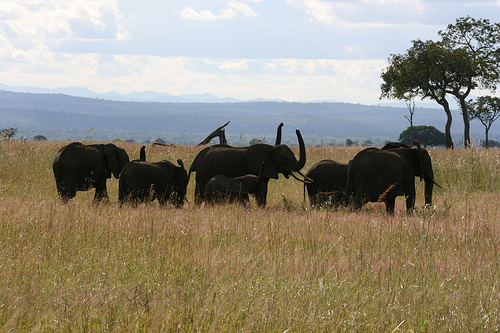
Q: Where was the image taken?
A: It was taken at the plain.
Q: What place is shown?
A: It is a plain.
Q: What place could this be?
A: It is a plain.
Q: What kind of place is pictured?
A: It is a plain.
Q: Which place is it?
A: It is a plain.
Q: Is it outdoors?
A: Yes, it is outdoors.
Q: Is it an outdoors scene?
A: Yes, it is outdoors.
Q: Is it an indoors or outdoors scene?
A: It is outdoors.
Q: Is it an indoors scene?
A: No, it is outdoors.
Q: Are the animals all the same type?
A: Yes, all the animals are elephants.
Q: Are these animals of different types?
A: No, all the animals are elephants.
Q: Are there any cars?
A: No, there are no cars.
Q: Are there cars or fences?
A: No, there are no cars or fences.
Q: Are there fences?
A: No, there are no fences.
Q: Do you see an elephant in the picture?
A: Yes, there is an elephant.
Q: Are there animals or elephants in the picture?
A: Yes, there is an elephant.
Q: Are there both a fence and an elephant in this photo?
A: No, there is an elephant but no fences.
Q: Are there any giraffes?
A: No, there are no giraffes.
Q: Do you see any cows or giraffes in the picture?
A: No, there are no giraffes or cows.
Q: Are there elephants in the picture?
A: Yes, there is an elephant.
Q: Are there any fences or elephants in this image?
A: Yes, there is an elephant.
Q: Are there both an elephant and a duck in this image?
A: No, there is an elephant but no ducks.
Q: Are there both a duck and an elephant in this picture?
A: No, there is an elephant but no ducks.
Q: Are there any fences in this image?
A: No, there are no fences.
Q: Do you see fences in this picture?
A: No, there are no fences.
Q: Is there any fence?
A: No, there are no fences.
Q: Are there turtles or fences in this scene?
A: No, there are no fences or turtles.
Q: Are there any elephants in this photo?
A: Yes, there is an elephant.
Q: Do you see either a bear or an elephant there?
A: Yes, there is an elephant.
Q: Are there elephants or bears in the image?
A: Yes, there is an elephant.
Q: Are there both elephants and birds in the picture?
A: No, there is an elephant but no birds.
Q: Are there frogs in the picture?
A: No, there are no frogs.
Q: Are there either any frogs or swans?
A: No, there are no frogs or swans.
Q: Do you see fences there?
A: No, there are no fences.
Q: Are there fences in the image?
A: No, there are no fences.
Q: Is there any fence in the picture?
A: No, there are no fences.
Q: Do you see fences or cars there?
A: No, there are no fences or cars.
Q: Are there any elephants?
A: Yes, there is an elephant.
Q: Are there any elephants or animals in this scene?
A: Yes, there is an elephant.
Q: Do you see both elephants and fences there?
A: No, there is an elephant but no fences.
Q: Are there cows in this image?
A: No, there are no cows.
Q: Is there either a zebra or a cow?
A: No, there are no cows or zebras.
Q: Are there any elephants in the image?
A: Yes, there is an elephant.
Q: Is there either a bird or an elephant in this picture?
A: Yes, there is an elephant.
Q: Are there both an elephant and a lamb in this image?
A: No, there is an elephant but no lambs.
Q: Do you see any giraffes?
A: No, there are no giraffes.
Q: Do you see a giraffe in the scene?
A: No, there are no giraffes.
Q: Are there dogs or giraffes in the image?
A: No, there are no giraffes or dogs.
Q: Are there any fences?
A: No, there are no fences.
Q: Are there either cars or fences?
A: No, there are no fences or cars.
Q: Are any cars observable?
A: No, there are no cars.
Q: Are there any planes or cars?
A: No, there are no cars or planes.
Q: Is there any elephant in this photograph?
A: Yes, there is an elephant.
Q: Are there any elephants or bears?
A: Yes, there is an elephant.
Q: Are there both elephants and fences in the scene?
A: No, there is an elephant but no fences.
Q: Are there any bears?
A: No, there are no bears.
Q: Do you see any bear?
A: No, there are no bears.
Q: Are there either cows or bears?
A: No, there are no bears or cows.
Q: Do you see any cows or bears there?
A: No, there are no bears or cows.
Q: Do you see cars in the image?
A: No, there are no cars.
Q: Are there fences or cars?
A: No, there are no cars or fences.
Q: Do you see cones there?
A: No, there are no cones.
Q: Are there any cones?
A: No, there are no cones.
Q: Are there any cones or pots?
A: No, there are no cones or pots.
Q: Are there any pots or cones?
A: No, there are no cones or pots.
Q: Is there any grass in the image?
A: Yes, there is grass.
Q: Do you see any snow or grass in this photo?
A: Yes, there is grass.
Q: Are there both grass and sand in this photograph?
A: No, there is grass but no sand.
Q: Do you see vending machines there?
A: No, there are no vending machines.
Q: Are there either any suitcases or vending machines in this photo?
A: No, there are no vending machines or suitcases.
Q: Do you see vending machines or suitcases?
A: No, there are no vending machines or suitcases.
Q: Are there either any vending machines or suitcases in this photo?
A: No, there are no vending machines or suitcases.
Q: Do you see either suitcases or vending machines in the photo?
A: No, there are no vending machines or suitcases.